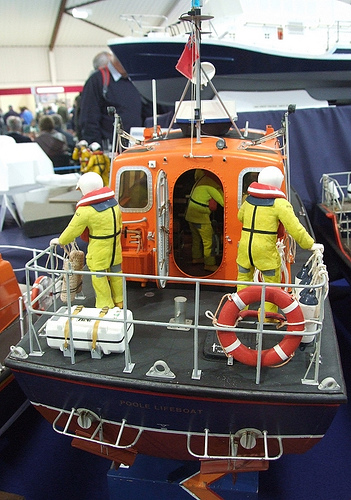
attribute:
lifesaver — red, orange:
[207, 282, 310, 372]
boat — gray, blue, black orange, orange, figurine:
[2, 31, 348, 448]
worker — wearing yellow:
[230, 171, 325, 314]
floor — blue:
[32, 445, 189, 498]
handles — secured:
[145, 226, 153, 250]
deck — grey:
[47, 265, 330, 390]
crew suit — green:
[67, 202, 144, 309]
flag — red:
[177, 31, 196, 85]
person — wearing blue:
[17, 103, 32, 130]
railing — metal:
[298, 242, 330, 388]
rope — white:
[311, 248, 328, 285]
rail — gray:
[23, 249, 78, 362]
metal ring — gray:
[309, 267, 334, 297]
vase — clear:
[149, 76, 161, 140]